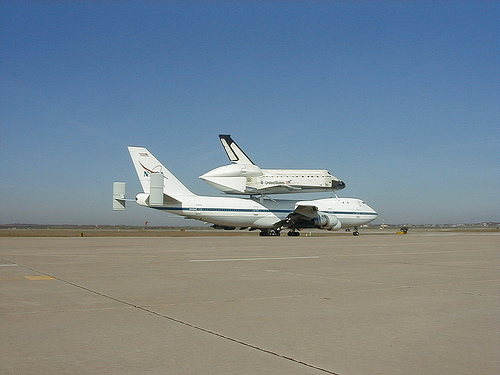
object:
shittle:
[199, 130, 348, 196]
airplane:
[108, 131, 378, 238]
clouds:
[0, 0, 500, 197]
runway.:
[0, 228, 500, 375]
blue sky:
[1, 0, 498, 227]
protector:
[198, 160, 246, 194]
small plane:
[197, 131, 349, 201]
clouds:
[0, 2, 499, 213]